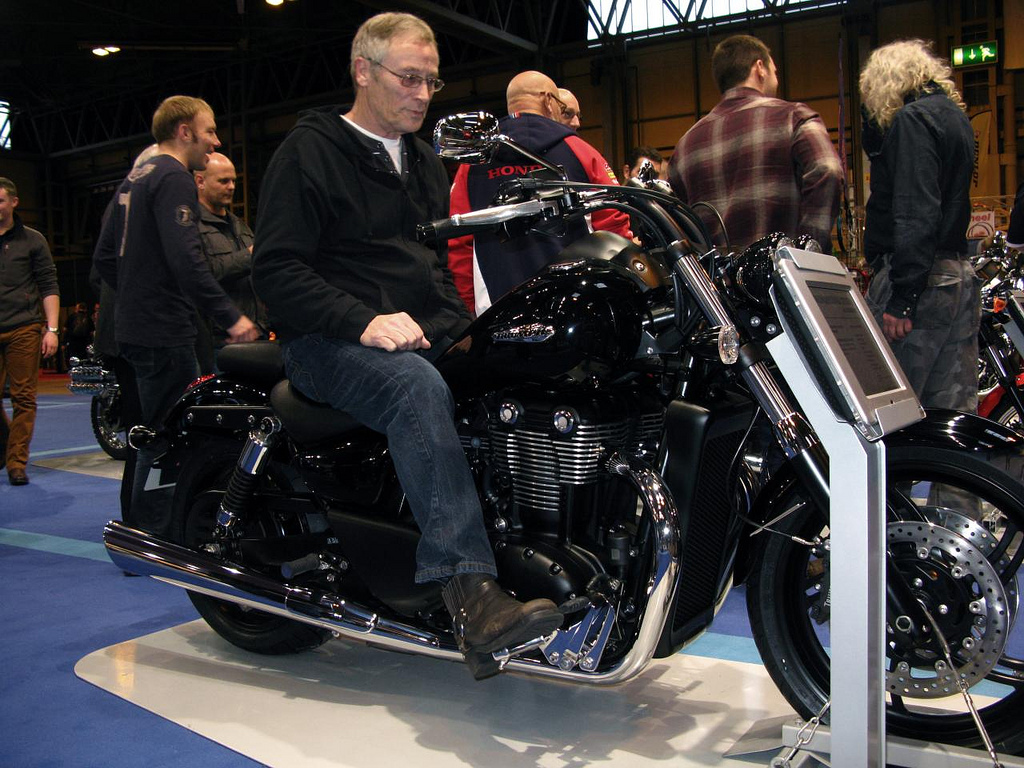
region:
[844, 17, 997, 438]
Person standing beside a motorcycle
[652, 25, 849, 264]
Person standing beside a motorcycle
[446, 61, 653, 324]
Person standing beside a motorcycle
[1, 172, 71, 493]
Person standing beside a motorcycle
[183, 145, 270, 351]
Person standing beside a motorcycle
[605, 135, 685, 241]
Person standing beside a motorcycle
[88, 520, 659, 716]
Silver muffler on a bike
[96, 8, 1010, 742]
Man sitting on a motorcycle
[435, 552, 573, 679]
Man wearing shoes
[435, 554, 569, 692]
Man is wearing shoes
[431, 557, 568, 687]
Man wearing brown shoes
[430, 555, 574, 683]
Man is wearing brown shoes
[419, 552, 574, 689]
Man wearing boots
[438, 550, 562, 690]
Man is wearing boots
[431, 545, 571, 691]
Man wearing brown boots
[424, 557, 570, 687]
Man is wearing brown boots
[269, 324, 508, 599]
Man wearing blue jeans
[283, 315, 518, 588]
Man is wearing blue jeans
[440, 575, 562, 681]
brown leather motorcycle boot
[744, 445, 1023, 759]
black rubber motorcycle tire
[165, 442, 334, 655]
black rubber motorcycle tire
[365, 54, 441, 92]
pair of eye glasses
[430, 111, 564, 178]
a motorcycle's rear view mirror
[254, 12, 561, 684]
man with glasses wearing sweatshirt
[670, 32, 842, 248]
man wearing a flannel shirt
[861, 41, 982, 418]
man wearing a black shirt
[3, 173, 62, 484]
man wearing brown pants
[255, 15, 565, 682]
A man is sitting on a motorcycle.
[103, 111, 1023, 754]
A motorcycle is black and shiny.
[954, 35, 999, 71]
The illuminated sign is green and white.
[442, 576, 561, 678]
The boot has a ring on the side.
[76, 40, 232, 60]
Two lights are on a beam.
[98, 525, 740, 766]
A shadow is under the machine parts.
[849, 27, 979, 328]
A person with long hair is wearing a black shirt.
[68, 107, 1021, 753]
More than one motorcycle is in the room.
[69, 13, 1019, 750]
man on a bike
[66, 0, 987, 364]
people in the background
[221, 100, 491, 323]
man wearing a black shirt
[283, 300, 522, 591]
man wearing blue jeans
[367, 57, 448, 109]
man wearing reading glasses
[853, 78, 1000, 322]
woman wearing a black shirt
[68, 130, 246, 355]
man wearing a blue shirt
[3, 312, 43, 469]
man wearing brown pants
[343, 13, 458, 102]
man has grey hair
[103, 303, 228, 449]
man wearing blue jeans